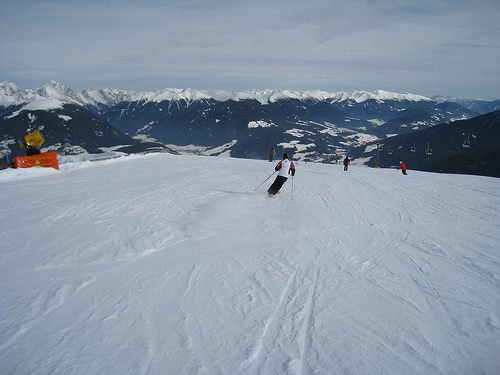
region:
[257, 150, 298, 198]
guy in a white jacket skiing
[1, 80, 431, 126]
chain of mountains with snow on the top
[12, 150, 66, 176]
a red sign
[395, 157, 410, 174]
a person with a red jacket skiing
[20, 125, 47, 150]
a yellow sign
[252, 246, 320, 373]
ski marks on the snow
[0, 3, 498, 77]
a cloudy sky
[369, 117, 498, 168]
a ski lift on the right side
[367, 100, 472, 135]
a couple of mountains with no snow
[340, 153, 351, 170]
a person in black skiing down the hill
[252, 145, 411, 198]
four people skiing on a snowy slope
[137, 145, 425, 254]
four skiers skiing on a wide mountain slope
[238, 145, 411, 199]
skiers on a snowy mountain slope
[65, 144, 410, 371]
people snow skiing at a resort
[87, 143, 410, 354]
tourists skiing at a ski resort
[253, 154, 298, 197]
a skier in a white winter coat skiing on the mountain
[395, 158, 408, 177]
a skier in a red coat skiing on a slope on the mountain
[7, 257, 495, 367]
snow covering the mountain slope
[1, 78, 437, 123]
snow covering the mountains' peaks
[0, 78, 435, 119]
snow on top of the mountains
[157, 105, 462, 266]
People are skiing down a hill.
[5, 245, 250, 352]
Snow is on the ground.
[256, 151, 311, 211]
A skier on the hill.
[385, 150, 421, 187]
A second skier on the hill.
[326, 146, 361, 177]
A third skier on the hill.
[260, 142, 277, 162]
A fourth skier on the hill.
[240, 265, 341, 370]
Ski tracks in the snow.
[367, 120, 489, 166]
A ski lift in the distance.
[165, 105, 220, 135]
The mountains look blue in the distance.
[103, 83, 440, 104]
The peaks of the mountains are covered in snow.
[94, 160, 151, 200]
ground covered in snow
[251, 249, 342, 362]
ski tracks in snow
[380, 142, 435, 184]
skier in red shirt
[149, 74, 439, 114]
mountain tops covered in snow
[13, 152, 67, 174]
orange plastic safety netting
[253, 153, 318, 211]
skier in white and red shirt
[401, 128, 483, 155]
grey metal ski lifts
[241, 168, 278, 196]
black metal ski pole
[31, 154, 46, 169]
yellow sign on orange safety netting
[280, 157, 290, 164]
black design on back of shirt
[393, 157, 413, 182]
This is a person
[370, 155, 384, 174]
This is a person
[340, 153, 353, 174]
This is a person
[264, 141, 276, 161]
This is a person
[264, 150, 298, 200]
This is a person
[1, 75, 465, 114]
These are ranges of mountains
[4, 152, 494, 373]
This is massive snow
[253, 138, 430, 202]
These are people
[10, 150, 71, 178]
This is a red structure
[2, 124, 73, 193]
This is a yellow and red structure